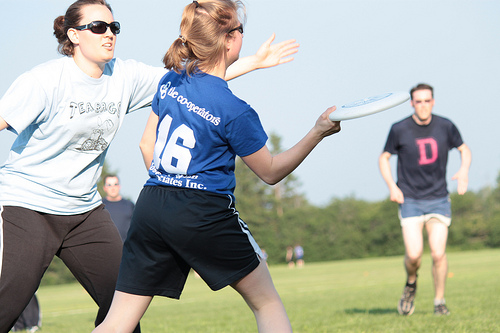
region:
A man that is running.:
[376, 80, 474, 315]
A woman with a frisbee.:
[90, 0, 412, 331]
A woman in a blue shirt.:
[0, 0, 169, 332]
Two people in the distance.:
[282, 238, 307, 269]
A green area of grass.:
[266, 250, 499, 331]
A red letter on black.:
[415, 133, 439, 164]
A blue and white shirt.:
[142, 64, 269, 187]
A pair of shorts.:
[111, 184, 268, 301]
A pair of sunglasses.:
[74, 18, 122, 35]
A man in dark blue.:
[100, 172, 136, 244]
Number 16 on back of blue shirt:
[145, 113, 195, 178]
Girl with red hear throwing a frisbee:
[86, 1, 418, 331]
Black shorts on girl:
[111, 183, 263, 303]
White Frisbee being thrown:
[326, 90, 412, 119]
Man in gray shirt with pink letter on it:
[375, 75, 473, 318]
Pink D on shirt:
[414, 136, 441, 167]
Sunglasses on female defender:
[66, 20, 122, 31]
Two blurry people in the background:
[281, 240, 301, 265]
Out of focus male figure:
[97, 171, 139, 247]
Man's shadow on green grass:
[340, 305, 413, 316]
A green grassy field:
[22, 254, 497, 330]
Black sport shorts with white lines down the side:
[112, 177, 267, 304]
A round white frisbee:
[315, 78, 408, 135]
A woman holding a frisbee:
[73, 0, 398, 331]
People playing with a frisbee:
[0, 2, 485, 325]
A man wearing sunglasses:
[375, 75, 473, 320]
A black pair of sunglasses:
[69, 15, 118, 40]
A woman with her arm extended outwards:
[2, 1, 299, 327]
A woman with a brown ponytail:
[0, 1, 159, 283]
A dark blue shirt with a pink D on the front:
[382, 118, 465, 209]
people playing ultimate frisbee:
[10, 16, 482, 298]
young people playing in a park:
[26, 13, 496, 294]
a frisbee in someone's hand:
[307, 83, 432, 180]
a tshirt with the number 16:
[130, 43, 267, 225]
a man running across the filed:
[350, 59, 480, 319]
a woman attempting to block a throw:
[17, 13, 144, 224]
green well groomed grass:
[300, 275, 331, 313]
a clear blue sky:
[326, 13, 431, 76]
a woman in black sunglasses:
[57, 13, 128, 58]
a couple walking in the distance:
[269, 242, 342, 285]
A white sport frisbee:
[325, 93, 415, 114]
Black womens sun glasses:
[70, 20, 120, 36]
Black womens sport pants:
[1, 196, 151, 331]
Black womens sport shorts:
[115, 175, 262, 315]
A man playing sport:
[382, 75, 470, 315]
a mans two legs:
[388, 188, 463, 318]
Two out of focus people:
[280, 240, 305, 267]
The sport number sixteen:
[148, 110, 201, 181]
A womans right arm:
[227, 91, 343, 186]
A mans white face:
[403, 80, 438, 125]